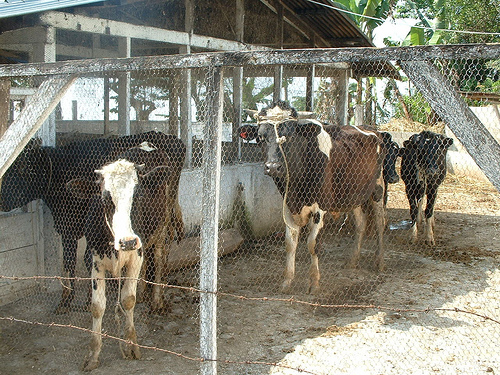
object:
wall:
[0, 158, 291, 329]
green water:
[226, 189, 262, 244]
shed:
[0, 0, 409, 316]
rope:
[234, 101, 308, 236]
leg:
[302, 205, 331, 297]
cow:
[228, 114, 399, 294]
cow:
[394, 129, 455, 247]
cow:
[53, 148, 185, 374]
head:
[233, 119, 321, 176]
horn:
[301, 111, 318, 119]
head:
[64, 158, 177, 253]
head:
[403, 129, 455, 175]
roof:
[0, 0, 394, 84]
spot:
[305, 117, 333, 157]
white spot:
[89, 161, 146, 248]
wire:
[7, 270, 495, 373]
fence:
[0, 43, 500, 375]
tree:
[356, 3, 493, 127]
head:
[384, 140, 407, 183]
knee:
[121, 295, 136, 312]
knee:
[85, 302, 107, 320]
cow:
[0, 127, 186, 317]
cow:
[380, 127, 407, 208]